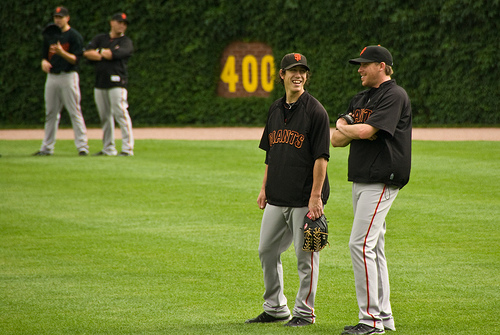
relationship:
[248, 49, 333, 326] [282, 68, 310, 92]
boy has a face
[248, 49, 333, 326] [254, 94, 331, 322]
boy wearing a uniform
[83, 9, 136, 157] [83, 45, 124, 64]
man folding h arms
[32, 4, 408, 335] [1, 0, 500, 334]
players standing in a field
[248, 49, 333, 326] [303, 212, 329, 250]
boy holding glove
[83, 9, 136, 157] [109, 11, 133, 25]
man wearing a cap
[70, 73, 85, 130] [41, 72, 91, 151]
stripe on side of trousers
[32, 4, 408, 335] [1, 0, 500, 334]
players standing on field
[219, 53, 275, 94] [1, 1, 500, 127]
number on fence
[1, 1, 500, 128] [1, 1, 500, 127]
ivy growing on fence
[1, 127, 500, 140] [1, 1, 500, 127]
warning track near fence